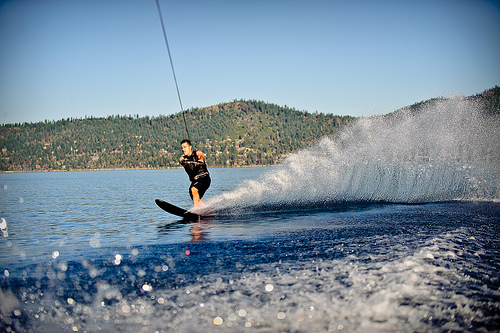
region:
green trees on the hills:
[1, 90, 498, 170]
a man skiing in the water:
[150, 133, 239, 232]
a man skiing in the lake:
[145, 131, 226, 226]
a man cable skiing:
[148, 119, 243, 238]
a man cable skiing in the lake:
[151, 120, 229, 229]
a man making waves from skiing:
[146, 95, 499, 242]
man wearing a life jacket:
[156, 126, 224, 221]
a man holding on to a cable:
[147, 0, 225, 227]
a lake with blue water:
[1, 169, 499, 328]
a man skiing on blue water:
[151, 125, 241, 227]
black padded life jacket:
[180, 152, 209, 177]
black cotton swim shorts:
[188, 175, 210, 198]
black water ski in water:
[156, 199, 215, 221]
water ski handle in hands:
[176, 156, 200, 165]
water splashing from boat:
[2, 221, 497, 331]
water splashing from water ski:
[191, 98, 498, 216]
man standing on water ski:
[157, 138, 214, 225]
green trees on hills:
[3, 100, 355, 163]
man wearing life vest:
[178, 137, 212, 207]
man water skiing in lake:
[155, 136, 215, 220]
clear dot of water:
[16, 194, 23, 205]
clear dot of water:
[1, 181, 10, 190]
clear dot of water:
[1, 217, 8, 231]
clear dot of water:
[3, 229, 8, 240]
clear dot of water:
[2, 268, 11, 278]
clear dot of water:
[263, 282, 277, 293]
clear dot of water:
[276, 308, 287, 319]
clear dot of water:
[238, 307, 247, 319]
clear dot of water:
[212, 313, 226, 325]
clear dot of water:
[129, 247, 139, 258]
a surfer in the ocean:
[147, 130, 227, 230]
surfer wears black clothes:
[174, 133, 216, 215]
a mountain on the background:
[1, 80, 493, 170]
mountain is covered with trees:
[1, 84, 499, 174]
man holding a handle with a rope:
[170, 0, 220, 210]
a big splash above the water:
[213, 82, 497, 229]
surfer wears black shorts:
[174, 135, 217, 216]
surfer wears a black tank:
[174, 131, 216, 216]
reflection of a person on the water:
[177, 218, 215, 248]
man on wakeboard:
[128, 126, 218, 227]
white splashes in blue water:
[248, 168, 302, 218]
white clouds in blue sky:
[362, 36, 404, 61]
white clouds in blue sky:
[402, 15, 443, 50]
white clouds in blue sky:
[37, 23, 82, 74]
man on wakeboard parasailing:
[170, 137, 217, 216]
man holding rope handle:
[181, 156, 201, 171]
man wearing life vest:
[181, 145, 209, 178]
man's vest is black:
[176, 149, 207, 176]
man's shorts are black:
[182, 169, 212, 204]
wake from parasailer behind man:
[197, 96, 497, 225]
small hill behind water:
[0, 77, 499, 180]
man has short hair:
[176, 135, 193, 145]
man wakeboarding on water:
[145, 125, 230, 246]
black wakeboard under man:
[145, 185, 252, 237]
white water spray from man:
[231, 91, 481, 221]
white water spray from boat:
[55, 215, 465, 325]